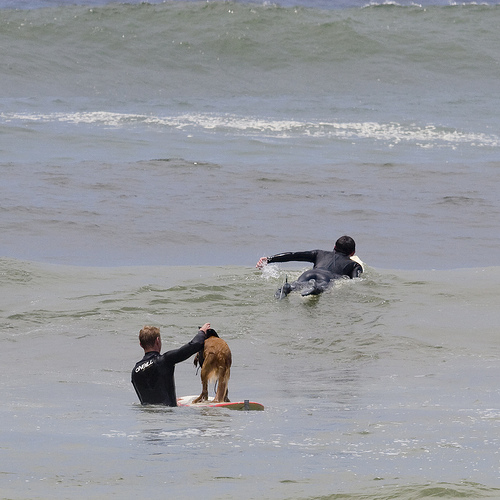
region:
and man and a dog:
[129, 302, 270, 421]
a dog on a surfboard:
[193, 323, 267, 418]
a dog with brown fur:
[204, 341, 240, 373]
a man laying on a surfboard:
[250, 217, 379, 317]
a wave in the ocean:
[74, 93, 265, 140]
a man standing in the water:
[115, 316, 185, 416]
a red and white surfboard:
[183, 386, 272, 424]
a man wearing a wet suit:
[255, 225, 377, 317]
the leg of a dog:
[194, 362, 214, 409]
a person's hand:
[198, 319, 215, 336]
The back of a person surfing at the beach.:
[251, 235, 362, 301]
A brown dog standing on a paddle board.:
[190, 321, 230, 401]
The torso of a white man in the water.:
[130, 320, 211, 410]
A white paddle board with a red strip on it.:
[175, 390, 262, 412]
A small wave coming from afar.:
[0, 107, 499, 151]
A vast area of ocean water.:
[1, 1, 498, 497]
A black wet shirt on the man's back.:
[129, 330, 208, 406]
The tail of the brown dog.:
[215, 358, 227, 400]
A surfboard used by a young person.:
[294, 253, 364, 298]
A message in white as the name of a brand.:
[133, 356, 155, 373]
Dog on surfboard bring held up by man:
[190, 322, 262, 421]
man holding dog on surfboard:
[128, 320, 270, 414]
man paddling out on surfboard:
[250, 219, 383, 308]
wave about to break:
[0, 5, 499, 110]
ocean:
[0, 0, 497, 231]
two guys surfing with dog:
[95, 222, 401, 434]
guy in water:
[123, 327, 183, 402]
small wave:
[7, 104, 494, 146]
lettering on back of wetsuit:
[130, 359, 159, 375]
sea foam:
[132, 411, 470, 468]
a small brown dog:
[184, 325, 241, 410]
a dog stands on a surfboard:
[169, 317, 269, 422]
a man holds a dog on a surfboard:
[119, 313, 269, 423]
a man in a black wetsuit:
[123, 320, 213, 411]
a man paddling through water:
[246, 225, 388, 317]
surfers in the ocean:
[7, 182, 494, 464]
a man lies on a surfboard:
[230, 215, 405, 316]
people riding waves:
[0, 215, 498, 437]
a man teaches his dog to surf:
[113, 310, 287, 431]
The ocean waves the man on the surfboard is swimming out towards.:
[4, 7, 492, 266]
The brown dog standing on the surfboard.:
[189, 326, 234, 401]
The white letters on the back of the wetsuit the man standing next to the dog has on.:
[124, 352, 157, 374]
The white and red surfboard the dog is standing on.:
[182, 389, 262, 420]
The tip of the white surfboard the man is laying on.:
[332, 252, 365, 269]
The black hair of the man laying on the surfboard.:
[332, 230, 356, 254]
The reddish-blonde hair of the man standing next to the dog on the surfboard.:
[132, 319, 164, 349]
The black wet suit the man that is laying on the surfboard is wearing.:
[294, 237, 364, 306]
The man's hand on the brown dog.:
[192, 313, 217, 336]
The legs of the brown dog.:
[191, 353, 236, 403]